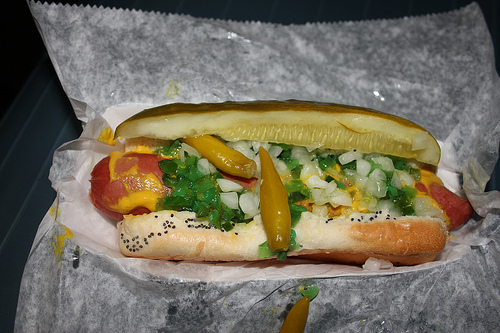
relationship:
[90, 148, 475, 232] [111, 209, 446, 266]
hotdog on bun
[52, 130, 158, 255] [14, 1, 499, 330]
mustard on paper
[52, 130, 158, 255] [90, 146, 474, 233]
mustard on wiener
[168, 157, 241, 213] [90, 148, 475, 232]
relish on hotdog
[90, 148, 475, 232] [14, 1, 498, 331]
hotdog on wrapper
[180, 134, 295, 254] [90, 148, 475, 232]
peppers around hotdog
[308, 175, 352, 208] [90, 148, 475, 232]
onions on hotdog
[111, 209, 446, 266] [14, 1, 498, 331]
bun in wrapper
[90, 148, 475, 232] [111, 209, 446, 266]
hotdog between bun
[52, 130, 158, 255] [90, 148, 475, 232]
mustard on hotdog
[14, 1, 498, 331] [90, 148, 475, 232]
wrapper holding hotdog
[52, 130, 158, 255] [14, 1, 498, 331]
mustard on wrapper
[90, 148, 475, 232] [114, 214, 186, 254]
hotdog with seeds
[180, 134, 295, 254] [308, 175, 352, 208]
peppers over onions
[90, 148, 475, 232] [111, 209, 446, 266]
hotdog inside bun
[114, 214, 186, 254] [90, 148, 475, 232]
seeds on hotdog